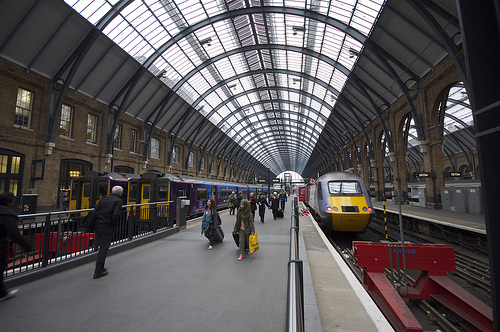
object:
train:
[301, 169, 377, 234]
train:
[122, 170, 285, 224]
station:
[1, 0, 500, 332]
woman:
[231, 197, 262, 263]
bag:
[248, 232, 261, 255]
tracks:
[336, 227, 484, 332]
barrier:
[350, 191, 500, 332]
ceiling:
[64, 0, 399, 176]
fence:
[0, 199, 178, 281]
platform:
[0, 192, 292, 332]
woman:
[201, 196, 220, 251]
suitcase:
[203, 226, 225, 244]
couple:
[256, 191, 280, 223]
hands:
[267, 205, 272, 210]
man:
[90, 185, 126, 279]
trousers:
[93, 230, 113, 272]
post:
[41, 212, 50, 268]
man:
[0, 190, 42, 302]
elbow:
[10, 231, 24, 245]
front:
[315, 170, 377, 236]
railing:
[284, 193, 309, 331]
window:
[327, 179, 365, 197]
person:
[278, 190, 290, 212]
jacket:
[278, 193, 287, 202]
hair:
[112, 185, 124, 194]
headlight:
[362, 206, 369, 212]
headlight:
[332, 206, 339, 212]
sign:
[418, 173, 430, 178]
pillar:
[414, 100, 449, 209]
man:
[269, 190, 282, 221]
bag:
[272, 207, 285, 219]